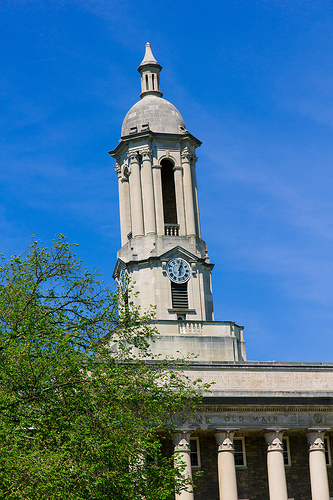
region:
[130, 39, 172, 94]
top part of the pillar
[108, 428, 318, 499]
a group of pillars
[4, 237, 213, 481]
a beautiful view of trees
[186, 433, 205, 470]
a small part of window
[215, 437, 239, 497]
a nice white pillar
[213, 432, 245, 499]
sun rise falling on pillar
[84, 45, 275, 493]
a very big pillar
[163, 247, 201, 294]
a display of wall clock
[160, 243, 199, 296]
a clock located in pillar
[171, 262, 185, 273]
hands in the clock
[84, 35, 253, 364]
tower on a building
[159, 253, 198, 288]
clock in front of tower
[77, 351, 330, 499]
an old building with columns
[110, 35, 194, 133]
dome of a tower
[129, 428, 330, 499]
five columns can be seen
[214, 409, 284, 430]
letters on the building says "Old Math"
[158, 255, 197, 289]
clock has roman numerals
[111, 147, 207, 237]
small columns under a dome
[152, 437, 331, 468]
white windows behind columns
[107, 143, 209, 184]
columns has decorations on top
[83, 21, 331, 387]
the tower reaches into the sky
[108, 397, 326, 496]
the building has pillars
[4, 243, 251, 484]
tree in front of the building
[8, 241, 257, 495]
tree leaves are green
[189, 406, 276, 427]
words over the pillars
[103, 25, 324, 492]
the building is grey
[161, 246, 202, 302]
clock on the tower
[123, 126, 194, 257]
a platform in the clock tower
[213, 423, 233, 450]
detailing on the pillar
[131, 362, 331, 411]
writing on the walls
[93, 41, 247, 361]
a tall concrete bell tower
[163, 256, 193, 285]
a clock on the tower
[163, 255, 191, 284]
a white and black clock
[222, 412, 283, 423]
concrete building name engraving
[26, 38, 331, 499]
a big historic building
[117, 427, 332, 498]
five concrete columns on the building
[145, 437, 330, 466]
a row of windows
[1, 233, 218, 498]
a tall green tree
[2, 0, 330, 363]
a clear blue sky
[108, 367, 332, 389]
words engraved into the concrete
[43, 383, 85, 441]
the leaves of a tree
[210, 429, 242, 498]
the pillar of a building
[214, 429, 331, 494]
pillars of a building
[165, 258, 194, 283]
the face of a clock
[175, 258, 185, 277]
the hands of a clock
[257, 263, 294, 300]
the clear blue sky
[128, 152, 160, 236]
pillar on the side of a building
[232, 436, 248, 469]
a window in a building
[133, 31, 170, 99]
a steeple of a building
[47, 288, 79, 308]
the branches of a tree